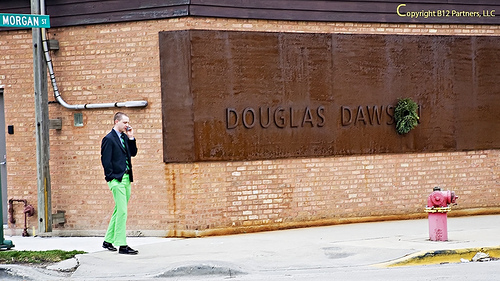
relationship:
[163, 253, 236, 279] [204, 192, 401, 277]
slope of sidewalk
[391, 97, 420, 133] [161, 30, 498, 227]
wreath on wall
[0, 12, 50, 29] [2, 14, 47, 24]
sign reads morgan st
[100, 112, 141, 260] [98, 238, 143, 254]
man wearing shoes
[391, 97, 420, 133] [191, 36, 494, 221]
wreath on building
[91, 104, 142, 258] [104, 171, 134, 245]
man wearing green pants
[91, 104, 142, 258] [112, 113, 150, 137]
man on cell phone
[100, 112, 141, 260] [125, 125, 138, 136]
man using cell phone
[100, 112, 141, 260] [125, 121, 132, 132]
man holding cell phone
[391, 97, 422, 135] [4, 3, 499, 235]
wreath hanging on a building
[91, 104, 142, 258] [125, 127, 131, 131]
man talking on cell phone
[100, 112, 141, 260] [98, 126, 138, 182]
man wearing a blue jacket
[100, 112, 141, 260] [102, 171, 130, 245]
man wearing pants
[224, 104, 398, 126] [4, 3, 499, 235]
name on building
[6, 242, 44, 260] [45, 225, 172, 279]
grass on sidewalk